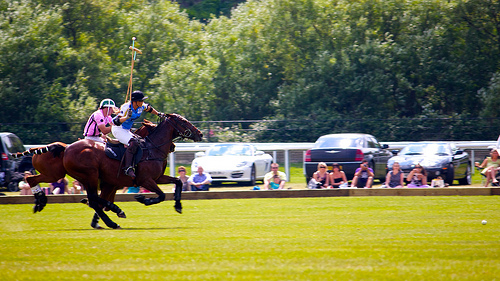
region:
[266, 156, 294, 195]
THAT IS A PERSON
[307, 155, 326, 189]
THAT IS A PERSON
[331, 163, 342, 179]
THAT IS A PERSON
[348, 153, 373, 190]
THAT IS A PERSON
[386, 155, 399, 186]
THAT IS A PERSON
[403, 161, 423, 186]
THAT IS A PERSON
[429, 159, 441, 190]
THAT IS A PERSON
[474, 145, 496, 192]
THAT IS A PERSON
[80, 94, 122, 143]
THAT IS A PERSON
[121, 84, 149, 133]
THAT IS A PERSON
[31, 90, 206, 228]
two horses competing against eachother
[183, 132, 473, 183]
parked cars behind the boundaries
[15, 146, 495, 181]
people setting outside boundaries of competition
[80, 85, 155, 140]
pink competing against blue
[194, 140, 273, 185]
white two door convertible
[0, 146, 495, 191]
people watching horses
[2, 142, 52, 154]
hair of tails are braided and bound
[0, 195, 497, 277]
very short green grass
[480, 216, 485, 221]
small white ball setting on the ground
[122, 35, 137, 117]
holds long pole or stick in hand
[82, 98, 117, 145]
Man in pink playing polo.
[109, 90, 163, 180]
man in blue playing polo.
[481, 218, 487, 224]
Polo ball is in the grass.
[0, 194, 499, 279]
The grass on the field is green.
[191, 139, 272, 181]
White car in the parking lot.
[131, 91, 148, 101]
Black helmet on the rider in blue.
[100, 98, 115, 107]
Green and white helmet on the rider in pink.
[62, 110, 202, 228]
Brown horse carrying the rider in blue.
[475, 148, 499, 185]
Woman in a green shirt sitting in a folding chair.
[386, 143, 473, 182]
Black car facing the polo field.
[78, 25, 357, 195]
the trees are behind the cars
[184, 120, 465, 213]
cars are in the parking lot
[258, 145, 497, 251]
the audience is watching the game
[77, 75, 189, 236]
men are on horses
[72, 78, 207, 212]
the men are on saddles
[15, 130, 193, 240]
the horses are running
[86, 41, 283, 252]
the men are holding maallets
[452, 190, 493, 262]
the ball is on the grass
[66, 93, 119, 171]
the man is wearing a pink shirt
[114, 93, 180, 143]
the man is wearing a blue shirt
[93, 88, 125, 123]
the head of a man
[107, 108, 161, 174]
the leg of a man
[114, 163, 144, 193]
the foot of a man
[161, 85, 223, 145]
the head of a horse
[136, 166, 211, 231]
the legs of a horse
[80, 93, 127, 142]
a man wearing a shirt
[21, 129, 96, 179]
the hail of a horse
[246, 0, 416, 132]
trees with green leaves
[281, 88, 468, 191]
people in the background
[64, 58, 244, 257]
a man riding a horse